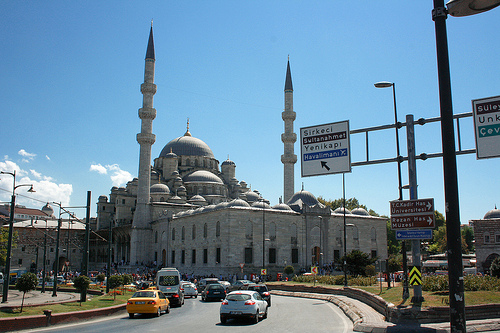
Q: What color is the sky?
A: Blue.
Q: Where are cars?
A: On the road.